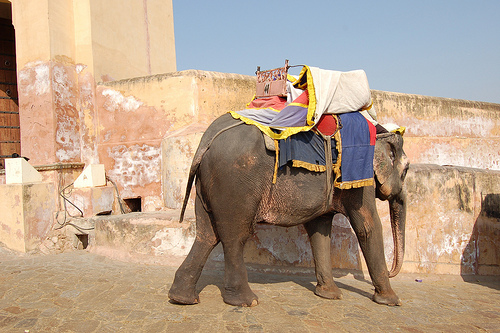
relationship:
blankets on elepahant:
[325, 111, 377, 190] [152, 103, 430, 302]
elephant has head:
[163, 104, 414, 306] [367, 113, 419, 211]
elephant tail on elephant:
[181, 144, 208, 224] [163, 104, 414, 306]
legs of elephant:
[305, 212, 407, 305] [163, 104, 414, 306]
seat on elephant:
[246, 56, 377, 198] [173, 97, 399, 282]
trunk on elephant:
[386, 191, 406, 278] [157, 83, 414, 313]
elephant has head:
[167, 104, 412, 306] [373, 123, 413, 279]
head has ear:
[373, 123, 413, 279] [368, 133, 405, 208]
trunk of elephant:
[381, 191, 411, 279] [157, 83, 414, 313]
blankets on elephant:
[227, 62, 377, 193] [163, 104, 414, 306]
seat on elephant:
[255, 56, 372, 115] [163, 104, 414, 306]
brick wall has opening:
[13, 4, 495, 259] [117, 193, 144, 210]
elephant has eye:
[163, 104, 414, 306] [399, 162, 413, 182]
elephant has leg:
[167, 104, 412, 306] [216, 225, 266, 304]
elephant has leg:
[167, 104, 412, 306] [181, 233, 214, 287]